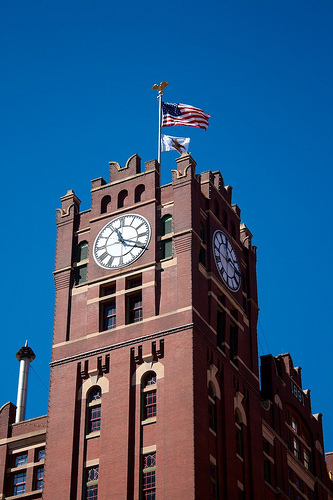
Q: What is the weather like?
A: It is clear.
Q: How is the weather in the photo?
A: It is clear.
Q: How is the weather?
A: It is clear.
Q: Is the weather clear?
A: Yes, it is clear.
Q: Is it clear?
A: Yes, it is clear.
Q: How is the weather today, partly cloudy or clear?
A: It is clear.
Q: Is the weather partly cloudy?
A: No, it is clear.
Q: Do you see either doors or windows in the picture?
A: Yes, there is a window.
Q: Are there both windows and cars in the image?
A: No, there is a window but no cars.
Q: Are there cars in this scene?
A: No, there are no cars.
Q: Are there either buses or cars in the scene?
A: No, there are no cars or buses.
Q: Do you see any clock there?
A: Yes, there is a clock.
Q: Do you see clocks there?
A: Yes, there is a clock.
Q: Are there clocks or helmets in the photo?
A: Yes, there is a clock.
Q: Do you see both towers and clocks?
A: Yes, there are both a clock and a tower.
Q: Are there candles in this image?
A: No, there are no candles.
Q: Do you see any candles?
A: No, there are no candles.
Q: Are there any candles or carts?
A: No, there are no candles or carts.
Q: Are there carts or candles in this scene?
A: No, there are no candles or carts.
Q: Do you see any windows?
A: Yes, there is a window.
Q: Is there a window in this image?
A: Yes, there is a window.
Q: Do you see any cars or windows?
A: Yes, there is a window.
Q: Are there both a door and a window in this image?
A: No, there is a window but no doors.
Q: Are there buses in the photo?
A: No, there are no buses.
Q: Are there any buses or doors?
A: No, there are no buses or doors.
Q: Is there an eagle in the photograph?
A: Yes, there is an eagle.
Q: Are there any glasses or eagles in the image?
A: Yes, there is an eagle.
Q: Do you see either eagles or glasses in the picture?
A: Yes, there is an eagle.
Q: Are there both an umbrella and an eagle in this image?
A: No, there is an eagle but no umbrellas.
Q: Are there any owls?
A: No, there are no owls.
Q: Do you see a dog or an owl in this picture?
A: No, there are no owls or dogs.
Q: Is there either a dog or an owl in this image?
A: No, there are no owls or dogs.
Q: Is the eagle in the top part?
A: Yes, the eagle is in the top of the image.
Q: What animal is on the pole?
A: The eagle is on the pole.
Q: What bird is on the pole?
A: The bird is an eagle.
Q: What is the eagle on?
A: The eagle is on the pole.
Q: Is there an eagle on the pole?
A: Yes, there is an eagle on the pole.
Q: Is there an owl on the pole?
A: No, there is an eagle on the pole.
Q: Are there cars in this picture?
A: No, there are no cars.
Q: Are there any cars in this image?
A: No, there are no cars.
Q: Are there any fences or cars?
A: No, there are no cars or fences.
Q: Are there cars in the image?
A: No, there are no cars.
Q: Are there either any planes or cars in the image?
A: No, there are no cars or planes.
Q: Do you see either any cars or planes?
A: No, there are no cars or planes.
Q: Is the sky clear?
A: Yes, the sky is clear.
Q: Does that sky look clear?
A: Yes, the sky is clear.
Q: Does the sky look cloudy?
A: No, the sky is clear.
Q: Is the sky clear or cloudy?
A: The sky is clear.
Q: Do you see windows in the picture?
A: Yes, there is a window.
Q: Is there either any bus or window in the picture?
A: Yes, there is a window.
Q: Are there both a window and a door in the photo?
A: No, there is a window but no doors.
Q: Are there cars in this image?
A: No, there are no cars.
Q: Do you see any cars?
A: No, there are no cars.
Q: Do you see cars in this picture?
A: No, there are no cars.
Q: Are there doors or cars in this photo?
A: No, there are no cars or doors.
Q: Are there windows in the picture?
A: Yes, there is a window.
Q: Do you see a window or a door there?
A: Yes, there is a window.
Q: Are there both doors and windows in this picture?
A: No, there is a window but no doors.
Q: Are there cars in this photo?
A: No, there are no cars.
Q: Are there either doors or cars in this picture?
A: No, there are no cars or doors.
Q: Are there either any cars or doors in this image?
A: No, there are no cars or doors.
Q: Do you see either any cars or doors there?
A: No, there are no cars or doors.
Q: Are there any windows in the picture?
A: Yes, there is a window.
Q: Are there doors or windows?
A: Yes, there is a window.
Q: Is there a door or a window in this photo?
A: Yes, there is a window.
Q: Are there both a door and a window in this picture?
A: No, there is a window but no doors.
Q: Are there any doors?
A: No, there are no doors.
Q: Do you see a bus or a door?
A: No, there are no doors or buses.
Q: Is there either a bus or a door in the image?
A: No, there are no doors or buses.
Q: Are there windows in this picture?
A: Yes, there is a window.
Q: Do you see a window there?
A: Yes, there is a window.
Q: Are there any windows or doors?
A: Yes, there is a window.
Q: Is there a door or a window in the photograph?
A: Yes, there is a window.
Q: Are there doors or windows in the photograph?
A: Yes, there is a window.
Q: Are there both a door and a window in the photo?
A: No, there is a window but no doors.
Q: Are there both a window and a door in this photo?
A: No, there is a window but no doors.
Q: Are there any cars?
A: No, there are no cars.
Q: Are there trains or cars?
A: No, there are no cars or trains.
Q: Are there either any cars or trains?
A: No, there are no cars or trains.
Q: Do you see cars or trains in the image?
A: No, there are no cars or trains.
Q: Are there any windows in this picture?
A: Yes, there is a window.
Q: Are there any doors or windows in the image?
A: Yes, there is a window.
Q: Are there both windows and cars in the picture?
A: No, there is a window but no cars.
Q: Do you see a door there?
A: No, there are no doors.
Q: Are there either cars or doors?
A: No, there are no doors or cars.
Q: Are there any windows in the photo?
A: Yes, there is a window.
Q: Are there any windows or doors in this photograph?
A: Yes, there is a window.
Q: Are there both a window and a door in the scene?
A: No, there is a window but no doors.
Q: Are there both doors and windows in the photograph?
A: No, there is a window but no doors.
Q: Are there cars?
A: No, there are no cars.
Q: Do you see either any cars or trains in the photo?
A: No, there are no cars or trains.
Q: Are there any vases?
A: No, there are no vases.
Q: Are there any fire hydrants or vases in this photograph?
A: No, there are no vases or fire hydrants.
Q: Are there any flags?
A: Yes, there is a flag.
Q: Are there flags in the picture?
A: Yes, there is a flag.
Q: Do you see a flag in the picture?
A: Yes, there is a flag.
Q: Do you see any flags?
A: Yes, there is a flag.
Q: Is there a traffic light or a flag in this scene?
A: Yes, there is a flag.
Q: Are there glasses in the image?
A: No, there are no glasses.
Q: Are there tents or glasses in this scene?
A: No, there are no glasses or tents.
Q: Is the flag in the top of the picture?
A: Yes, the flag is in the top of the image.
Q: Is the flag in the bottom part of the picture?
A: No, the flag is in the top of the image.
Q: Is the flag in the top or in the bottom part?
A: The flag is in the top of the image.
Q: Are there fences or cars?
A: No, there are no cars or fences.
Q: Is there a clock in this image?
A: Yes, there is a clock.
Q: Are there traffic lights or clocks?
A: Yes, there is a clock.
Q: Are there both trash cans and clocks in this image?
A: No, there is a clock but no trash cans.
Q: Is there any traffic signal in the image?
A: No, there are no traffic lights.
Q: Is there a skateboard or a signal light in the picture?
A: No, there are no traffic lights or skateboards.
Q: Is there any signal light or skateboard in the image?
A: No, there are no traffic lights or skateboards.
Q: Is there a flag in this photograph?
A: Yes, there is a flag.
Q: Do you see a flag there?
A: Yes, there is a flag.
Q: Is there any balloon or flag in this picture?
A: Yes, there is a flag.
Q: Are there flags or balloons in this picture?
A: Yes, there is a flag.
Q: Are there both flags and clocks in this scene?
A: Yes, there are both a flag and a clock.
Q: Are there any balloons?
A: No, there are no balloons.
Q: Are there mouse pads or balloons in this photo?
A: No, there are no balloons or mouse pads.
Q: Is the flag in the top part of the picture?
A: Yes, the flag is in the top of the image.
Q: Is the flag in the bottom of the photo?
A: No, the flag is in the top of the image.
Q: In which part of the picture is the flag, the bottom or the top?
A: The flag is in the top of the image.